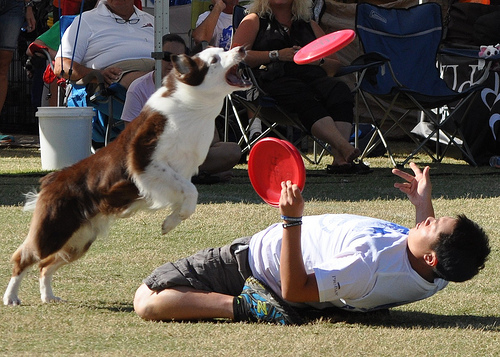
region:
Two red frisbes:
[231, 133, 327, 210]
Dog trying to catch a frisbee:
[14, 42, 262, 298]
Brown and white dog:
[21, 22, 282, 237]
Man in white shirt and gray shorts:
[142, 208, 472, 355]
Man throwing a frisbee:
[157, 85, 464, 326]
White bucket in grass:
[26, 92, 116, 193]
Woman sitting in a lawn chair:
[235, 5, 375, 167]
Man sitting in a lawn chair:
[52, 6, 179, 164]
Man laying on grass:
[143, 201, 480, 353]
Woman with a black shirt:
[243, 5, 398, 148]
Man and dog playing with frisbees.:
[4, 27, 489, 328]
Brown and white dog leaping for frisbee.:
[0, 26, 359, 310]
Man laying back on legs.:
[126, 232, 325, 336]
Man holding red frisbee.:
[246, 136, 318, 274]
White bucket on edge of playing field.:
[30, 96, 103, 179]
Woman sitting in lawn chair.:
[236, 9, 393, 180]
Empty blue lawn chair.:
[351, 6, 471, 167]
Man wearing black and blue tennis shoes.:
[238, 271, 307, 331]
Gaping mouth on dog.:
[222, 47, 260, 99]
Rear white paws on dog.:
[1, 288, 65, 310]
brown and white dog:
[0, 34, 270, 304]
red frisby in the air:
[281, 23, 381, 70]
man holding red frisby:
[126, 120, 489, 343]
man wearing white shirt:
[239, 130, 499, 310]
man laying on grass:
[122, 125, 498, 333]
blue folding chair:
[338, 3, 478, 168]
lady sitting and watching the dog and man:
[227, 2, 401, 193]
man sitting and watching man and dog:
[72, 6, 214, 153]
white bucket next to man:
[23, 100, 103, 172]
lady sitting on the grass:
[119, 29, 254, 184]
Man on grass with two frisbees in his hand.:
[131, 135, 497, 325]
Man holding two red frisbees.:
[130, 135, 490, 327]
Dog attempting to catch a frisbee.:
[2, 27, 357, 308]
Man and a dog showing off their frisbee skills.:
[1, 28, 491, 329]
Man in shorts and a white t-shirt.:
[131, 133, 491, 326]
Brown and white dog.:
[4, 43, 254, 303]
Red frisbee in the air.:
[292, 29, 356, 64]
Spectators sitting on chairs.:
[2, 1, 499, 173]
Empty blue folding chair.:
[342, 0, 483, 171]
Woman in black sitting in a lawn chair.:
[229, 1, 372, 172]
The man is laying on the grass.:
[122, 157, 498, 313]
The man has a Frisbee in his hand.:
[231, 135, 337, 211]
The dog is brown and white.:
[32, 12, 244, 287]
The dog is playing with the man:
[38, 13, 394, 355]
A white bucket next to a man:
[39, 77, 116, 178]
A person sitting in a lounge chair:
[237, 18, 389, 163]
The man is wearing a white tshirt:
[259, 220, 431, 316]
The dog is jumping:
[48, 61, 205, 289]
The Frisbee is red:
[283, 28, 373, 80]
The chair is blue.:
[348, 13, 458, 145]